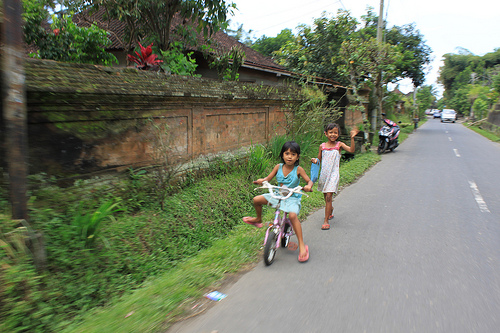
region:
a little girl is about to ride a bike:
[237, 135, 316, 268]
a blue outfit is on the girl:
[258, 164, 304, 214]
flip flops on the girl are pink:
[236, 210, 314, 265]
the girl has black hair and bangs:
[278, 140, 302, 168]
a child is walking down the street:
[307, 120, 361, 230]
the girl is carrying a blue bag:
[306, 149, 328, 188]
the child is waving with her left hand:
[306, 116, 362, 233]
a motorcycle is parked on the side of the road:
[373, 112, 404, 159]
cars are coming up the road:
[424, 103, 471, 178]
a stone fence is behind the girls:
[9, 53, 390, 219]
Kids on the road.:
[230, 115, 447, 290]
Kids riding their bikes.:
[250, 56, 425, 289]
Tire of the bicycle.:
[239, 213, 301, 264]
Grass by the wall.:
[146, 157, 236, 244]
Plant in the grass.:
[45, 191, 157, 249]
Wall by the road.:
[135, 33, 388, 216]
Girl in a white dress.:
[297, 102, 374, 189]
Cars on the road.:
[395, 48, 462, 142]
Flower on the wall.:
[108, 28, 221, 96]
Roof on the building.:
[78, 2, 300, 94]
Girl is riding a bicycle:
[240, 140, 312, 265]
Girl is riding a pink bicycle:
[237, 139, 314, 266]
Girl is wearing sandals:
[237, 213, 314, 263]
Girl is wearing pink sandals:
[240, 212, 312, 265]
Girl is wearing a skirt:
[257, 188, 301, 213]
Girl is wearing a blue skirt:
[260, 189, 305, 213]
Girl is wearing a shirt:
[270, 162, 304, 193]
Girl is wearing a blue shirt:
[274, 159, 304, 191]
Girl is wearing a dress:
[315, 143, 345, 195]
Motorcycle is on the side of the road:
[372, 115, 402, 155]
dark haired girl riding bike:
[230, 128, 322, 289]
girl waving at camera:
[299, 112, 368, 234]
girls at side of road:
[240, 115, 373, 292]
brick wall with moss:
[9, 52, 327, 207]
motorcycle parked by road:
[370, 104, 452, 190]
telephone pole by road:
[355, 3, 431, 164]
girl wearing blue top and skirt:
[238, 133, 322, 270]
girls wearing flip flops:
[238, 117, 370, 273]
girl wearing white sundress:
[306, 112, 368, 232]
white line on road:
[438, 115, 498, 261]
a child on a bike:
[232, 130, 314, 267]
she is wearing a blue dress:
[259, 159, 304, 225]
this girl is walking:
[310, 114, 355, 230]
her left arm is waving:
[336, 120, 366, 154]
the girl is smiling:
[319, 117, 341, 148]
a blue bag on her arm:
[305, 152, 326, 184]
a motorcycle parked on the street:
[372, 114, 401, 156]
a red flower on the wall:
[127, 37, 161, 73]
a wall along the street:
[17, 52, 374, 209]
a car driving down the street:
[439, 105, 460, 130]